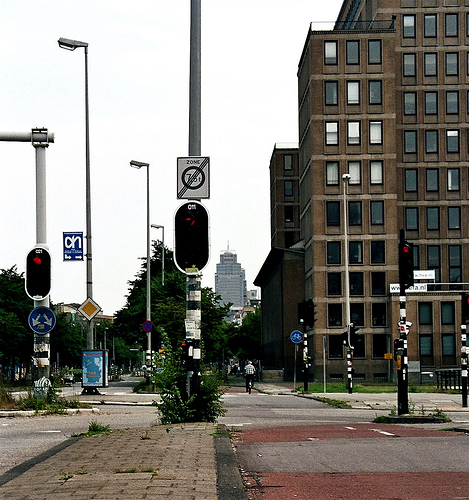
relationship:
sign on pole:
[290, 329, 302, 342] [291, 344, 300, 385]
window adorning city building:
[323, 39, 337, 65] [257, 0, 469, 389]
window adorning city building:
[345, 40, 357, 65] [257, 0, 469, 389]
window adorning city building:
[366, 40, 382, 65] [257, 0, 469, 389]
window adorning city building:
[345, 82, 358, 106] [257, 0, 469, 389]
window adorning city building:
[324, 80, 337, 106] [257, 0, 469, 389]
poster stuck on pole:
[181, 314, 196, 337] [185, 0, 202, 385]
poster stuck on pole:
[191, 347, 202, 360] [185, 0, 202, 385]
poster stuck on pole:
[185, 345, 193, 356] [185, 0, 202, 385]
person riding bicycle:
[242, 357, 258, 392] [244, 378, 255, 395]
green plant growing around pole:
[151, 365, 231, 427] [185, 0, 202, 385]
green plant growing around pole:
[12, 375, 87, 419] [29, 125, 50, 396]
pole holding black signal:
[185, 0, 202, 385] [174, 203, 208, 271]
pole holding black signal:
[29, 125, 50, 396] [25, 245, 51, 297]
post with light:
[72, 54, 100, 296] [52, 34, 89, 50]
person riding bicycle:
[244, 360, 257, 392] [244, 372, 256, 394]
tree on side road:
[118, 244, 241, 393] [56, 372, 148, 391]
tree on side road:
[1, 263, 32, 379] [56, 372, 148, 391]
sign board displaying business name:
[388, 282, 426, 293] [383, 281, 434, 303]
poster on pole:
[185, 311, 200, 340] [185, 0, 202, 385]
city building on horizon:
[257, 13, 464, 280] [7, 78, 275, 272]